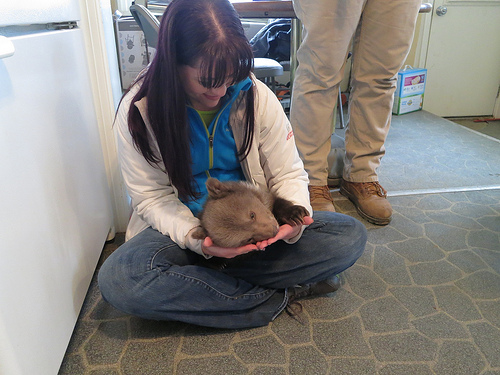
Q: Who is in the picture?
A: A girl and person.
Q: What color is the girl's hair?
A: Black.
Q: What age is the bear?
A: Baby age.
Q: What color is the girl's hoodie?
A: Blue.